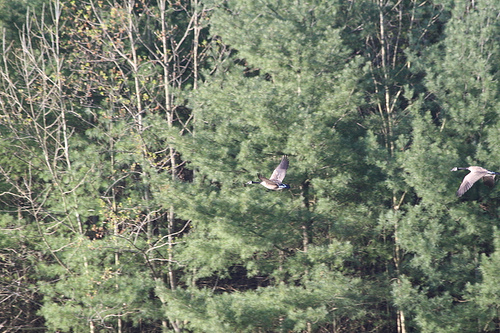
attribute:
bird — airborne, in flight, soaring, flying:
[244, 154, 293, 192]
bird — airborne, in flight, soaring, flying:
[451, 162, 500, 197]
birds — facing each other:
[245, 153, 499, 201]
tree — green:
[374, 11, 500, 332]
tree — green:
[132, 0, 392, 332]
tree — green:
[29, 127, 164, 332]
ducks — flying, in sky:
[245, 155, 500, 199]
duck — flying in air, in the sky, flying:
[248, 155, 292, 194]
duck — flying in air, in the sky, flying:
[451, 162, 497, 200]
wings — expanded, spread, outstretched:
[269, 156, 290, 182]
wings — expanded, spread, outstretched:
[254, 171, 279, 191]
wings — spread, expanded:
[455, 171, 484, 197]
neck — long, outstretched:
[456, 162, 467, 173]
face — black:
[449, 164, 459, 176]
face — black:
[245, 177, 253, 187]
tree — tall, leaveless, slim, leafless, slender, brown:
[3, 2, 208, 332]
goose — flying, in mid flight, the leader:
[241, 157, 294, 198]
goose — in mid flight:
[449, 159, 496, 199]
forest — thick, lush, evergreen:
[1, 1, 499, 332]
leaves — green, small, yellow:
[6, 4, 180, 122]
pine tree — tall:
[157, 8, 397, 332]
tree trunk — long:
[373, 23, 411, 332]